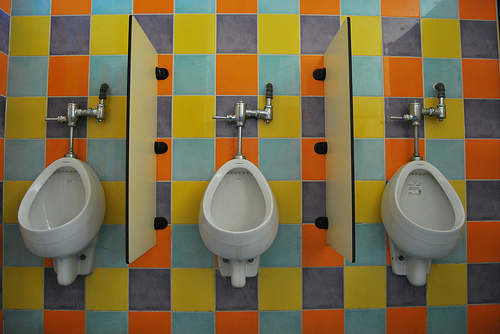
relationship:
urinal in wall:
[14, 155, 108, 288] [7, 8, 479, 332]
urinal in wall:
[195, 157, 281, 291] [7, 8, 479, 332]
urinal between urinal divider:
[195, 157, 281, 291] [123, 11, 161, 270]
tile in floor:
[172, 264, 211, 311] [2, 2, 497, 331]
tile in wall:
[256, 135, 302, 184] [7, 15, 492, 313]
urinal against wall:
[198, 103, 298, 285] [152, 2, 331, 330]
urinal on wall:
[195, 157, 281, 291] [7, 8, 479, 332]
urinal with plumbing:
[14, 155, 108, 288] [209, 83, 280, 148]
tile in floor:
[256, 135, 302, 184] [3, 15, 470, 315]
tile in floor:
[256, 135, 302, 184] [35, 6, 458, 312]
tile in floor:
[256, 134, 304, 184] [47, 8, 411, 218]